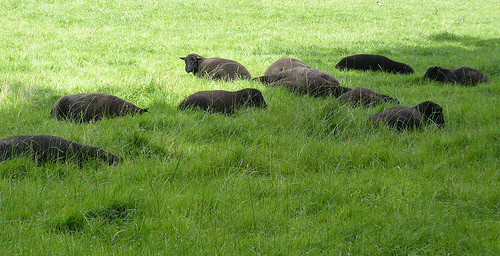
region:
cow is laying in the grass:
[177, 88, 267, 115]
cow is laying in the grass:
[53, 91, 148, 121]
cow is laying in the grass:
[3, 135, 123, 168]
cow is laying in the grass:
[369, 104, 444, 131]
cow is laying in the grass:
[335, 54, 416, 76]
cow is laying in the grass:
[423, 65, 489, 87]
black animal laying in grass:
[1, 132, 123, 166]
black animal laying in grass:
[49, 91, 149, 123]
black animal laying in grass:
[175, 86, 265, 116]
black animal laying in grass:
[370, 98, 446, 130]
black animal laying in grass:
[339, 87, 397, 108]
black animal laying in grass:
[255, 68, 343, 96]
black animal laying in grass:
[268, 56, 309, 77]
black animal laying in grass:
[180, 50, 249, 77]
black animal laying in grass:
[338, 55, 413, 76]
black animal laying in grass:
[422, 64, 488, 85]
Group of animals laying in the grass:
[0, 52, 493, 169]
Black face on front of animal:
[178, 50, 202, 72]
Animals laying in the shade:
[252, 55, 496, 130]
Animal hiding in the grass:
[367, 100, 446, 134]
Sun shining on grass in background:
[0, 2, 497, 94]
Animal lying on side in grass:
[254, 56, 341, 99]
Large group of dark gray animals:
[0, 52, 493, 169]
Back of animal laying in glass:
[49, 94, 75, 120]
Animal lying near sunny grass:
[334, 53, 414, 75]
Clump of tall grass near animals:
[301, 97, 351, 141]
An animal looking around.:
[178, 51, 255, 84]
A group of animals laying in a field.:
[1, 41, 490, 166]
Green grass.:
[123, 132, 498, 254]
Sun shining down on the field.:
[0, 0, 498, 45]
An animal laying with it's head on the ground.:
[45, 88, 152, 123]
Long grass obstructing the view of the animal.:
[356, 107, 443, 133]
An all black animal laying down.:
[336, 50, 418, 76]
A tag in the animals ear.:
[192, 53, 202, 59]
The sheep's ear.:
[176, 54, 190, 61]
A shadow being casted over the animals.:
[0, 94, 498, 252]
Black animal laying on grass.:
[180, 50, 251, 85]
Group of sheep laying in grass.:
[2, 49, 487, 174]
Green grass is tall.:
[5, 165, 497, 251]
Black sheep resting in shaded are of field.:
[6, 83, 498, 250]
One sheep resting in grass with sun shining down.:
[4, 5, 252, 75]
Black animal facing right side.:
[174, 82, 270, 119]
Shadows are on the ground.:
[392, 5, 498, 57]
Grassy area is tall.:
[183, 110, 355, 157]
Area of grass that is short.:
[1, 3, 154, 59]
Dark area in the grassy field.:
[50, 185, 152, 235]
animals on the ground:
[16, 28, 476, 218]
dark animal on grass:
[160, 33, 247, 88]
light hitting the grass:
[51, 19, 152, 72]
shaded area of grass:
[169, 168, 294, 232]